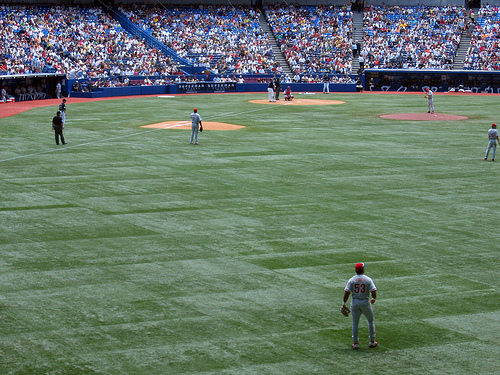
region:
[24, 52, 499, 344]
Baseball players in action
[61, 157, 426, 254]
Green baseball field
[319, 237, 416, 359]
A baseball player in white uniform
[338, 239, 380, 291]
A player wearing a red hat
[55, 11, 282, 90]
Baseball fans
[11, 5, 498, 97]
Game spectators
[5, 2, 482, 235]
Baseball stadium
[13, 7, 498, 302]
Major league baseball match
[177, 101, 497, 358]
Three baseball fielders on right side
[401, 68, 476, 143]
Pitcher ready to bowl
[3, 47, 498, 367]
a professional baseball field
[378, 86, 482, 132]
a red pitchers mound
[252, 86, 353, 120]
home plate on field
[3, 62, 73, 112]
one team's dug out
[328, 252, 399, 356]
a man in sports uniform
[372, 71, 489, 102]
a bunch of guys in white pants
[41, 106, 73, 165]
a referee in black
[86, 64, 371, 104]
a low blue wall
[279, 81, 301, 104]
a baseball catcher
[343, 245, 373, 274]
a red baseball cap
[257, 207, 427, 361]
a baseball player in outfield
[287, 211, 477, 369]
this is an outfield position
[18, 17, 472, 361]
inside a baseball stadium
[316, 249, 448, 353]
player number is 53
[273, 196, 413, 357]
his hat is red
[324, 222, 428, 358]
the baseball player has a glove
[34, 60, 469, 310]
the sport is baseball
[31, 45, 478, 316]
the players are alert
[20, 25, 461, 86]
there are many people in the stadium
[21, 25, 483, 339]
this is major league baseball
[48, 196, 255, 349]
patch of baseball field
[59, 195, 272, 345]
patch of green baseball field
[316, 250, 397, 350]
baseball player on field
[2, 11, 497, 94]
crowd at baseball game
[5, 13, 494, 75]
spectators at baseball game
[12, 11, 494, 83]
crowd at baseball stadium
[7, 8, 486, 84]
spectators at baseball stadium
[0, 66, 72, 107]
dugout area at baseball game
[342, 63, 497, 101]
large dugout at stadium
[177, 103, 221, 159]
ball player standing on field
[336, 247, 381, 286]
A man with a red hat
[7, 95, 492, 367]
A large field with dirt bases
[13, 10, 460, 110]
A stadium full of people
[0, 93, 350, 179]
There are white lines in the grass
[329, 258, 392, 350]
The man is wearing a white uniform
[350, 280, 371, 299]
Number 53 on the uniform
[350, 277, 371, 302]
The number 53 is red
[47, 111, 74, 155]
A man wearing all black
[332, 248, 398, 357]
The man stands on the field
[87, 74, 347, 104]
A blue wall in front of the stands